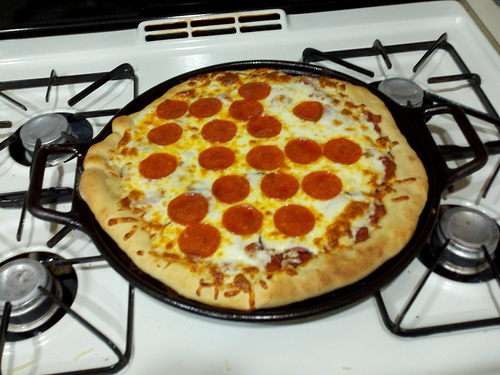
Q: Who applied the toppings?
A: Pizza consumer.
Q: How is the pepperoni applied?
A: Unevenly.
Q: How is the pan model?
A: Dual handled.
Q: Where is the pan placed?
A: Stove.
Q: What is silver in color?
A: The gas burners.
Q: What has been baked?
A: Pizza.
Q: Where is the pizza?
A: On top of the stove.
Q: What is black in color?
A: The grate on the burners.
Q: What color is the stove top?
A: White.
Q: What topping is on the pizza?
A: Pepperoni.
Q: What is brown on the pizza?
A: The crust.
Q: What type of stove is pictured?
A: A gas stove.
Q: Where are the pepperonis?
A: On the pizza.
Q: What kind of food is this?
A: Pizza.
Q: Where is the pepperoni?
A: On the pizza.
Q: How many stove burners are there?
A: Four.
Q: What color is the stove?
A: White.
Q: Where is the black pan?
A: Under the pizza.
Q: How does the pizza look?
A: Freshly cooked.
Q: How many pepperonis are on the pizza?
A: Twenty.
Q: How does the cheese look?
A: Melted.